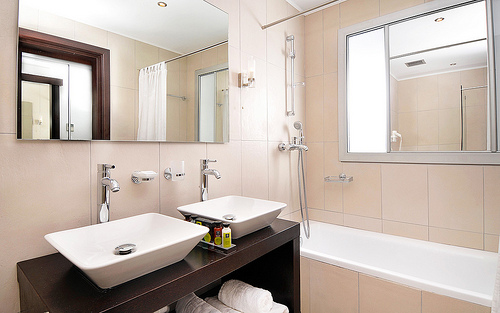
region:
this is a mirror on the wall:
[22, 12, 225, 140]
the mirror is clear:
[23, 12, 229, 134]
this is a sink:
[82, 212, 171, 276]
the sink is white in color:
[102, 222, 178, 254]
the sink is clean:
[98, 216, 168, 254]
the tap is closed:
[95, 163, 121, 214]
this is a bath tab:
[323, 234, 490, 281]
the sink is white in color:
[391, 258, 488, 276]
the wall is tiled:
[355, 184, 498, 226]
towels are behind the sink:
[224, 279, 275, 311]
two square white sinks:
[40, 191, 289, 284]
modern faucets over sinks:
[87, 152, 228, 207]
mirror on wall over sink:
[11, 8, 240, 157]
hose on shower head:
[290, 159, 316, 249]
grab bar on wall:
[272, 29, 309, 124]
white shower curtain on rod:
[130, 52, 182, 155]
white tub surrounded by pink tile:
[317, 216, 481, 288]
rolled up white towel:
[213, 274, 268, 310]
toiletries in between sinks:
[175, 212, 244, 255]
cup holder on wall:
[161, 150, 193, 187]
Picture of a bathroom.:
[16, 12, 459, 297]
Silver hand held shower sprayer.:
[281, 109, 323, 220]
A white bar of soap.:
[126, 161, 167, 191]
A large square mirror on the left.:
[10, 7, 241, 149]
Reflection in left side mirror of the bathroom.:
[32, 9, 222, 136]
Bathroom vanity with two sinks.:
[13, 207, 315, 310]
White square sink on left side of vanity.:
[40, 207, 209, 287]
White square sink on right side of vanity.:
[179, 181, 291, 239]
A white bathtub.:
[313, 211, 474, 305]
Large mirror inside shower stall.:
[332, 7, 499, 179]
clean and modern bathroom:
[22, 10, 472, 297]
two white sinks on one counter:
[40, 165, 295, 275]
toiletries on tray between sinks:
[170, 196, 240, 258]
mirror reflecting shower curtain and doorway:
[16, 5, 236, 150]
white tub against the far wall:
[281, 197, 491, 304]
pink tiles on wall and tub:
[325, 167, 425, 307]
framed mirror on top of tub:
[325, 12, 496, 239]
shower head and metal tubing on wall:
[280, 110, 327, 240]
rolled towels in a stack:
[166, 265, 301, 307]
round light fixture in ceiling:
[140, 0, 172, 25]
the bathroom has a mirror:
[14, 0, 238, 151]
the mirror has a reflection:
[22, 25, 228, 136]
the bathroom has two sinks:
[10, 163, 291, 263]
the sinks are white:
[37, 185, 287, 267]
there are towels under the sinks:
[159, 267, 300, 311]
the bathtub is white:
[306, 214, 498, 291]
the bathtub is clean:
[300, 214, 497, 306]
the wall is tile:
[318, 162, 498, 242]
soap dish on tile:
[323, 160, 374, 192]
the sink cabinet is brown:
[29, 225, 306, 310]